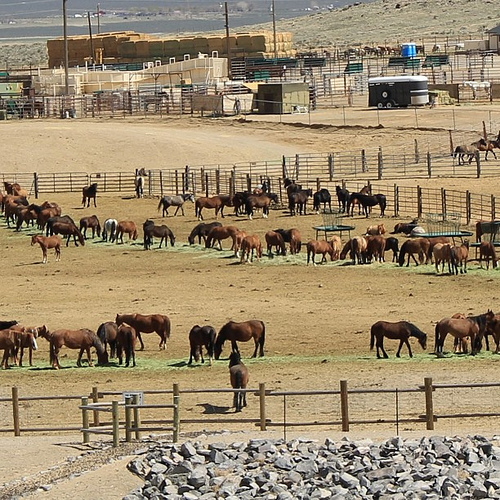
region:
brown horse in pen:
[220, 301, 275, 365]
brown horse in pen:
[363, 312, 419, 362]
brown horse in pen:
[441, 316, 473, 374]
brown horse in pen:
[50, 326, 95, 376]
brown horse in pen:
[2, 325, 41, 347]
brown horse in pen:
[36, 234, 71, 269]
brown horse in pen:
[112, 225, 151, 248]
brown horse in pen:
[244, 195, 273, 217]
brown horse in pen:
[354, 184, 394, 206]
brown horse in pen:
[309, 186, 341, 212]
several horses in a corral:
[0, 172, 448, 392]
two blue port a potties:
[395, 36, 428, 61]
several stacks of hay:
[50, 28, 272, 55]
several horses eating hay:
[20, 314, 301, 374]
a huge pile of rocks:
[162, 433, 483, 498]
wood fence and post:
[142, 136, 419, 198]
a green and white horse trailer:
[358, 62, 443, 117]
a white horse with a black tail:
[95, 215, 120, 238]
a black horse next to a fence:
[348, 192, 390, 213]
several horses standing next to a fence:
[252, 177, 357, 209]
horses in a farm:
[2, 5, 492, 487]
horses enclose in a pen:
[0, 135, 498, 445]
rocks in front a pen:
[127, 389, 492, 499]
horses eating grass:
[361, 301, 498, 365]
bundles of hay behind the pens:
[35, 15, 299, 66]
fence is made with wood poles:
[1, 383, 489, 431]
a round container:
[355, 65, 439, 115]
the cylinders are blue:
[394, 38, 422, 63]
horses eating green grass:
[175, 316, 275, 367]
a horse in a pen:
[21, 226, 69, 261]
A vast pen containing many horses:
[13, 185, 498, 419]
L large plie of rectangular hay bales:
[44, 25, 322, 80]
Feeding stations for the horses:
[307, 200, 472, 266]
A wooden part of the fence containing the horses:
[0, 381, 492, 438]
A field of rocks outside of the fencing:
[150, 435, 499, 498]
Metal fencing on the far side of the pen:
[13, 169, 498, 228]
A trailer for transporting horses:
[349, 62, 449, 109]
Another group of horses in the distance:
[293, 38, 454, 62]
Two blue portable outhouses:
[394, 39, 427, 63]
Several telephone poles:
[54, 0, 309, 112]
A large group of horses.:
[7, 179, 499, 376]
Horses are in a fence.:
[3, 161, 496, 424]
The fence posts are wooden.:
[245, 380, 451, 431]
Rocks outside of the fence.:
[142, 430, 498, 497]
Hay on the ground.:
[46, 330, 483, 373]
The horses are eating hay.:
[16, 191, 488, 301]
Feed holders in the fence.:
[303, 203, 473, 245]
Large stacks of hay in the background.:
[31, 26, 276, 78]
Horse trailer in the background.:
[361, 74, 438, 109]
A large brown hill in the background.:
[263, 0, 495, 52]